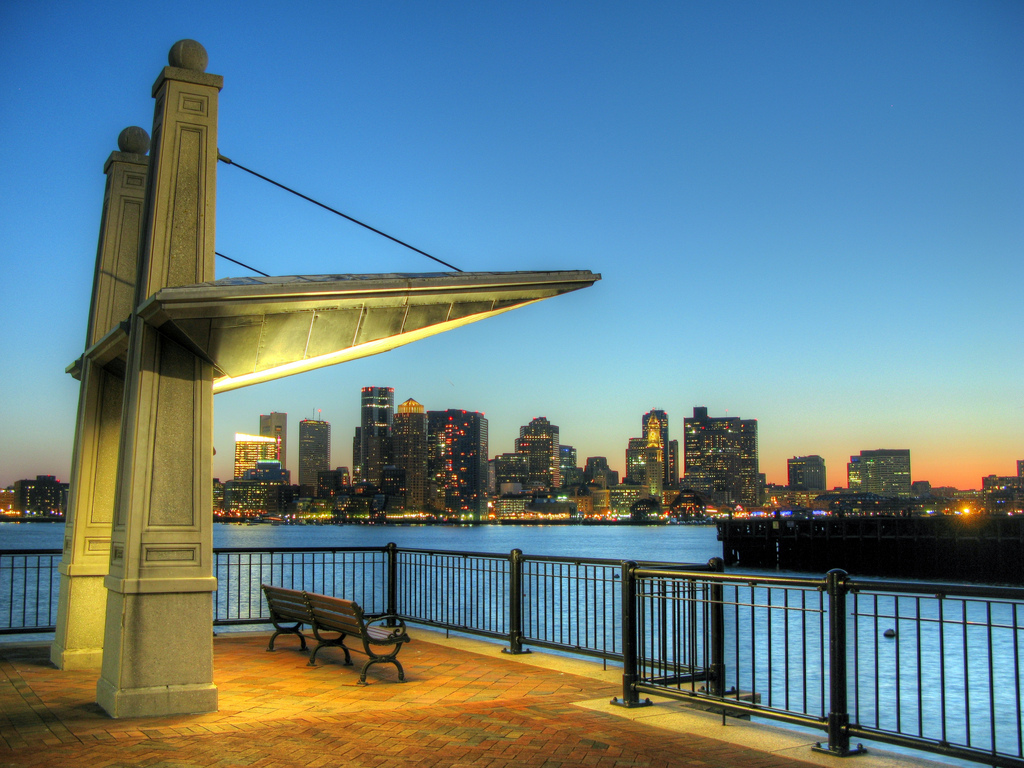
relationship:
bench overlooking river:
[244, 555, 405, 690] [6, 482, 1016, 757]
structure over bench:
[60, 30, 629, 756] [257, 579, 407, 688]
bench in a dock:
[260, 582, 412, 686] [210, 533, 524, 719]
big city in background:
[205, 390, 1005, 565] [192, 270, 986, 768]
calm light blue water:
[220, 438, 992, 711] [525, 540, 698, 683]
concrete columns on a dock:
[134, 224, 214, 745] [266, 585, 606, 768]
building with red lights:
[404, 434, 467, 530] [437, 427, 472, 495]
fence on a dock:
[0, 540, 1024, 768] [385, 585, 651, 707]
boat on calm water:
[676, 449, 1022, 627] [702, 527, 1001, 586]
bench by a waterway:
[260, 582, 412, 686] [354, 553, 592, 768]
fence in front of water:
[0, 540, 1024, 768] [534, 507, 992, 663]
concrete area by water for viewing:
[45, 656, 746, 768] [475, 555, 1013, 768]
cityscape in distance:
[322, 444, 936, 492] [151, 243, 1022, 768]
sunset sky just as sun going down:
[50, 129, 973, 482] [283, 464, 923, 614]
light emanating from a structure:
[171, 343, 489, 542] [54, 248, 579, 768]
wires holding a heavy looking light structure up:
[190, 164, 543, 301] [134, 302, 336, 577]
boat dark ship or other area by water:
[713, 509, 1022, 587] [603, 399, 1021, 661]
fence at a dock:
[316, 552, 952, 741] [0, 612, 972, 768]